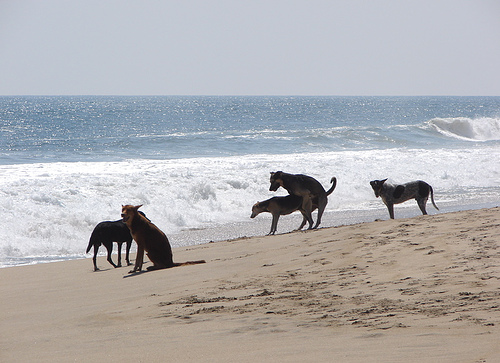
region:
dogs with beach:
[78, 160, 446, 285]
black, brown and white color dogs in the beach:
[87, 161, 455, 296]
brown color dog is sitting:
[118, 201, 206, 282]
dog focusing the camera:
[369, 175, 444, 217]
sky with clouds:
[95, 22, 452, 84]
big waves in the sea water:
[51, 145, 482, 188]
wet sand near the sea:
[154, 280, 456, 352]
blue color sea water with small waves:
[60, 88, 391, 152]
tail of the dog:
[75, 238, 94, 255]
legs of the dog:
[89, 255, 124, 276]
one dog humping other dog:
[229, 160, 342, 229]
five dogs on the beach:
[76, 151, 448, 281]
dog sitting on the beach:
[115, 199, 202, 271]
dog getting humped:
[242, 199, 299, 234]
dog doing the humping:
[267, 174, 337, 221]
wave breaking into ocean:
[414, 115, 496, 146]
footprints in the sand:
[185, 205, 497, 327]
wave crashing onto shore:
[14, 158, 486, 257]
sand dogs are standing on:
[21, 198, 487, 362]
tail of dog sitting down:
[172, 258, 203, 273]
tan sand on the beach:
[0, 206, 498, 361]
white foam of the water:
[0, 144, 498, 263]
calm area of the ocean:
[0, 95, 496, 157]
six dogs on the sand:
[85, 171, 440, 277]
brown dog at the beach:
[121, 203, 208, 274]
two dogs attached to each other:
[249, 168, 336, 236]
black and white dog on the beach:
[367, 178, 441, 216]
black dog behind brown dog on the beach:
[86, 211, 149, 271]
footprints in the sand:
[146, 205, 498, 329]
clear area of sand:
[1, 254, 163, 361]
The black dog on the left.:
[81, 210, 145, 263]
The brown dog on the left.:
[120, 193, 186, 269]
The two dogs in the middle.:
[237, 158, 341, 238]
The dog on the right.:
[370, 175, 436, 215]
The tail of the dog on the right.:
[419, 178, 441, 210]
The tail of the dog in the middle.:
[320, 175, 339, 196]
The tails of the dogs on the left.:
[85, 228, 202, 280]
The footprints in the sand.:
[177, 208, 497, 323]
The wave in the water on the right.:
[388, 105, 498, 157]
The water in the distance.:
[2, 95, 499, 142]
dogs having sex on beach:
[258, 141, 325, 231]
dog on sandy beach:
[72, 214, 131, 273]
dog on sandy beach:
[129, 200, 192, 277]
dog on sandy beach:
[234, 190, 305, 229]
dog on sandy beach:
[275, 157, 357, 223]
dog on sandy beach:
[360, 169, 452, 223]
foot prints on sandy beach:
[168, 242, 488, 342]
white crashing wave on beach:
[63, 162, 473, 228]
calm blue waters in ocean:
[27, 85, 467, 151]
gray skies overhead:
[17, 5, 447, 129]